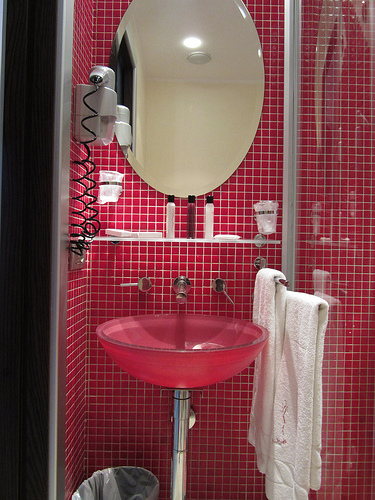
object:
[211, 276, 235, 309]
knob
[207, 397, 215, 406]
tile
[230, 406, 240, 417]
tile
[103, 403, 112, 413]
tile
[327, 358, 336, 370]
tile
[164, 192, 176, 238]
bottles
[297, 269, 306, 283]
tile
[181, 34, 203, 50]
light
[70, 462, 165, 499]
can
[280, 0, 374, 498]
shower door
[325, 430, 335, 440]
tile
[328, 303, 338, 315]
tile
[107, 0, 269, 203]
mirror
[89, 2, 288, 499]
wall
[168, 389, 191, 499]
pipe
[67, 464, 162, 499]
trash bag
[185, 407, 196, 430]
piece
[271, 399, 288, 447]
design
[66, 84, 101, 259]
cord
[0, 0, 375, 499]
restroom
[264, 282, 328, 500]
towels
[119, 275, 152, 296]
knob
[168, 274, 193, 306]
faucet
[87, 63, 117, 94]
hair drier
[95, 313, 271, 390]
sink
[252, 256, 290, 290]
rack